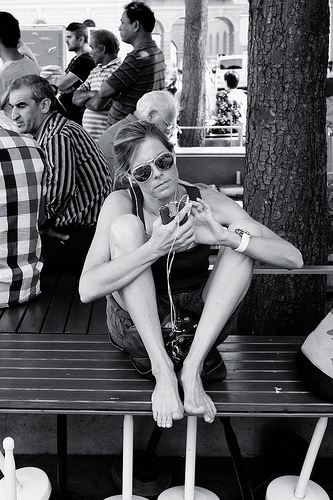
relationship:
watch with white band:
[231, 228, 251, 253] [232, 233, 251, 252]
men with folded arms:
[63, 65, 126, 109] [50, 52, 149, 105]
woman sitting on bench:
[103, 142, 227, 312] [1, 331, 321, 436]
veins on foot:
[153, 384, 202, 403] [134, 357, 226, 489]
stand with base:
[212, 54, 252, 141] [175, 124, 243, 149]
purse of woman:
[122, 310, 238, 381] [78, 118, 304, 428]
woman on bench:
[78, 118, 304, 428] [0, 333, 331, 499]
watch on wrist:
[231, 227, 251, 253] [220, 227, 239, 249]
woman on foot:
[78, 118, 304, 428] [149, 367, 185, 429]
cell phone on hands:
[158, 201, 197, 255] [149, 196, 226, 254]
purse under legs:
[133, 306, 235, 387] [109, 218, 255, 428]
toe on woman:
[188, 401, 207, 419] [78, 118, 304, 428]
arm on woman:
[184, 187, 303, 268] [78, 118, 304, 428]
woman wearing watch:
[78, 118, 304, 428] [235, 218, 250, 266]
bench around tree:
[0, 247, 330, 498] [213, 1, 331, 255]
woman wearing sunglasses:
[78, 118, 304, 428] [126, 147, 175, 183]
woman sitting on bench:
[78, 118, 304, 428] [0, 247, 330, 498]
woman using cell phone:
[78, 118, 304, 428] [158, 201, 197, 255]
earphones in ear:
[127, 156, 189, 332] [121, 167, 141, 185]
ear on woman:
[121, 167, 141, 185] [78, 118, 304, 428]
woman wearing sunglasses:
[78, 118, 304, 428] [133, 149, 174, 182]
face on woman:
[128, 134, 177, 199] [78, 118, 304, 428]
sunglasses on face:
[133, 149, 174, 182] [128, 134, 177, 199]